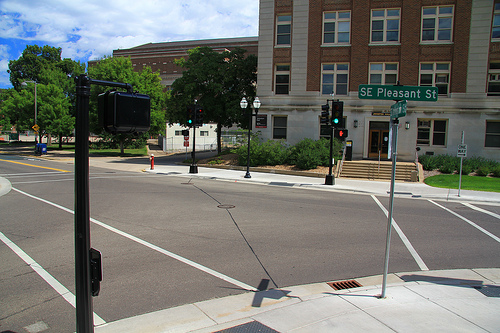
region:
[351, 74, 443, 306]
green and white street sign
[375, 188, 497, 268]
two parallel white lines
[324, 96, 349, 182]
traffic light shining green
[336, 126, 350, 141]
red pedestrian signal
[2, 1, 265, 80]
bright white clouds in the sky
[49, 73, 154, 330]
short black pole on the corner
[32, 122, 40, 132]
yellow and black sign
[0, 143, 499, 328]
no cars on the road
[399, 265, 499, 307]
shadow on the sidewalk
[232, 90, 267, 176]
black lamp post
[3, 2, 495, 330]
An urban street scene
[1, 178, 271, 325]
This is a crosswalk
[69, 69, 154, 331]
A crosswalk signal light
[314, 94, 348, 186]
A traffic light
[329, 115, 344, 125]
The traffic light is green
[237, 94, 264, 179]
This is a lamp post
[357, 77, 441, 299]
A street intersection sign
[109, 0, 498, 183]
Buildings are across the street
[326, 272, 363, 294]
A drainage grate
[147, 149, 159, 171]
A red fire hydrant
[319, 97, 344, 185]
Black traffic light with green light lit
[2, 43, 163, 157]
Tall green trees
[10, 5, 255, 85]
Blue sky with white clouds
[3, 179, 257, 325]
White cross walk lines on street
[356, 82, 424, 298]
Green and white street sign on pole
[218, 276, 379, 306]
Shadow of street sign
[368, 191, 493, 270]
White cross walk on street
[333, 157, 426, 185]
Tan steps in front of building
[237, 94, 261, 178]
White and black street light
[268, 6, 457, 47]
Row of windows on building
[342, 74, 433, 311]
street sign on the corner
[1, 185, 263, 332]
two parallel white lines on the ground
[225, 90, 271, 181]
small black street lamp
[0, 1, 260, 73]
big white clouds in the sky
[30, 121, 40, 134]
black and yellow sign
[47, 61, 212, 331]
short black pole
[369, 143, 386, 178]
railing along the stairs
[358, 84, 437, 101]
the green street sign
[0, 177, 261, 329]
the white lines for the crosswalk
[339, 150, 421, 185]
the stairs to the building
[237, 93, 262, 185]
the black street light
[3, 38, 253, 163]
the tall green trees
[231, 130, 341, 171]
the green bushes in front of the building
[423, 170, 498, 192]
the green grass in front of the building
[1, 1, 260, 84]
the clouds in the blue sky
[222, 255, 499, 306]
the shadows on the ground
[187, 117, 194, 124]
the green traffic light